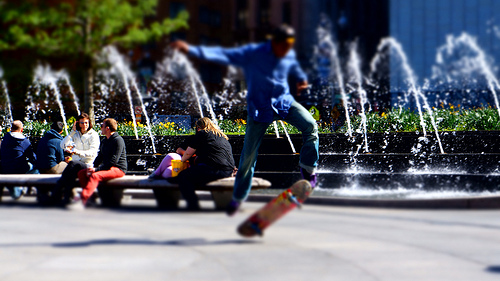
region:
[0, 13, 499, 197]
the water splashing in the air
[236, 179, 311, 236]
the skateboard under the skater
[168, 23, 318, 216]
the skater in mid air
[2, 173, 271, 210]
the cement benches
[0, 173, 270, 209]
the cement benches near the skater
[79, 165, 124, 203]
the man's long pants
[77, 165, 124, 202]
the red pants on the man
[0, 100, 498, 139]
the greenery near the water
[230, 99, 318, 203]
the blue jeans on the skater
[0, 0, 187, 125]
the tree in the background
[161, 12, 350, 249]
Person in the foreground is skateboarding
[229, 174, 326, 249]
Skateboard is in the air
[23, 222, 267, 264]
Person is casting a shadow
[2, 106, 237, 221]
People in the background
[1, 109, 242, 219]
People are sitting down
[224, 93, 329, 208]
Young man is wearing blue jeans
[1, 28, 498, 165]
Water Fountain in the background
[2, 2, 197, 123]
A tall tree in the background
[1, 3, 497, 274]
Photo was taken in the daytime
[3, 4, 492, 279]
Photo was taken outdoors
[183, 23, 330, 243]
Kid doing a ollie on a skateboard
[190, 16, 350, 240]
Kid skateboarding in front of a fountain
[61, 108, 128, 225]
Couple sitting on a bench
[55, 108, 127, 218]
Two people talking on a bench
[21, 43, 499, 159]
Beautiful fountain in a park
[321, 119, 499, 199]
Water plashing on the steps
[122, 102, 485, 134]
Yellow flowers growing in a fountain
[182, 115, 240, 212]
Woman enjoying the fountain in the park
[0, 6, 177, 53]
Pine tree growing in the park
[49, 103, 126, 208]
Two people relaxing in front of the fountain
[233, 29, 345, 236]
mabn on a skating board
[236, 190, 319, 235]
skating board is red in color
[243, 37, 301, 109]
shirt is blue in color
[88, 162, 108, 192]
pants are red in color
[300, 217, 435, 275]
floor is grey n color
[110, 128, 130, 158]
sweater is black in color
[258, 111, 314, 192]
pants are faded blue in color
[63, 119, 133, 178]
two ladies are seated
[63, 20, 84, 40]
green leaves on the tree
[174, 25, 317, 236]
skateboarder flying in the air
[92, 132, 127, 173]
black top man is wearing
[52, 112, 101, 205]
woman wearing a white jacket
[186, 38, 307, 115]
blue shirt skateboarder is wearing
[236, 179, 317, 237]
red skateboard boy is on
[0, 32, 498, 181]
water fountains in the background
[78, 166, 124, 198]
dark orange pants the man is wearing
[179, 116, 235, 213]
woman sitting on the bench by herself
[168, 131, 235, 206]
black outfit woman is wearing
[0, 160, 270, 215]
bench people are sitting on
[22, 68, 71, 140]
fountain stream by the skate boarder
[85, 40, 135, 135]
fountain stream by the skate boarder